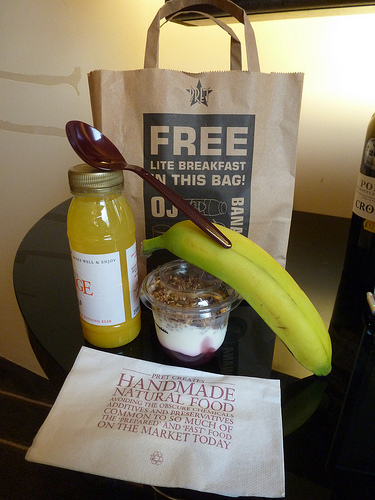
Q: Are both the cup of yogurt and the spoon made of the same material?
A: Yes, both the cup and the spoon are made of plastic.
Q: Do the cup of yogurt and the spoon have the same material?
A: Yes, both the cup and the spoon are made of plastic.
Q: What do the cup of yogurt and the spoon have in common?
A: The material, both the cup and the spoon are plastic.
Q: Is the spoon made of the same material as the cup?
A: Yes, both the spoon and the cup are made of plastic.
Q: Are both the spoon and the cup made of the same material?
A: Yes, both the spoon and the cup are made of plastic.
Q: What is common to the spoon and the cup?
A: The material, both the spoon and the cup are plastic.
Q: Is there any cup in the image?
A: Yes, there is a cup.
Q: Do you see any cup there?
A: Yes, there is a cup.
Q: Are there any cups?
A: Yes, there is a cup.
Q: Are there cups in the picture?
A: Yes, there is a cup.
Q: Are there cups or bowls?
A: Yes, there is a cup.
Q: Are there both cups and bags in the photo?
A: Yes, there are both a cup and a bag.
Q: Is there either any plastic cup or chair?
A: Yes, there is a plastic cup.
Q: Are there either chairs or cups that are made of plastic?
A: Yes, the cup is made of plastic.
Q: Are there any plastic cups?
A: Yes, there is a cup that is made of plastic.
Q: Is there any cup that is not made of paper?
A: Yes, there is a cup that is made of plastic.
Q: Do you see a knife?
A: No, there are no knives.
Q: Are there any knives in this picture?
A: No, there are no knives.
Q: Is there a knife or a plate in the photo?
A: No, there are no knives or plates.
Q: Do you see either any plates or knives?
A: No, there are no knives or plates.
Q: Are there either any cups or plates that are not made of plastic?
A: No, there is a cup but it is made of plastic.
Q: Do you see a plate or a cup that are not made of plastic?
A: No, there is a cup but it is made of plastic.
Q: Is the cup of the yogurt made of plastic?
A: Yes, the cup is made of plastic.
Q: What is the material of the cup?
A: The cup is made of plastic.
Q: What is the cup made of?
A: The cup is made of plastic.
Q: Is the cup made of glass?
A: No, the cup is made of plastic.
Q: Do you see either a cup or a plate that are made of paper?
A: No, there is a cup but it is made of plastic.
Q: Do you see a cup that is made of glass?
A: No, there is a cup but it is made of plastic.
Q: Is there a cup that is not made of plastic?
A: No, there is a cup but it is made of plastic.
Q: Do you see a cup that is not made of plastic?
A: No, there is a cup but it is made of plastic.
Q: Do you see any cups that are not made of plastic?
A: No, there is a cup but it is made of plastic.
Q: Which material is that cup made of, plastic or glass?
A: The cup is made of plastic.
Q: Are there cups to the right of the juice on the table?
A: Yes, there is a cup to the right of the juice.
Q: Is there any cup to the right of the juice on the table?
A: Yes, there is a cup to the right of the juice.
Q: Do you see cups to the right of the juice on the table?
A: Yes, there is a cup to the right of the juice.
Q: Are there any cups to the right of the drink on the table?
A: Yes, there is a cup to the right of the juice.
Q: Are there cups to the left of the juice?
A: No, the cup is to the right of the juice.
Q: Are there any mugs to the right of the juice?
A: No, there is a cup to the right of the juice.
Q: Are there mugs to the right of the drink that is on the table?
A: No, there is a cup to the right of the juice.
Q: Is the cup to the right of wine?
A: No, the cup is to the right of the juice.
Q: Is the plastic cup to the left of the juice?
A: No, the cup is to the right of the juice.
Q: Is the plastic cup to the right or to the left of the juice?
A: The cup is to the right of the juice.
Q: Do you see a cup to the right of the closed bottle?
A: Yes, there is a cup to the right of the bottle.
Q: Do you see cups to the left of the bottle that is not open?
A: No, the cup is to the right of the bottle.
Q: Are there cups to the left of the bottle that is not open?
A: No, the cup is to the right of the bottle.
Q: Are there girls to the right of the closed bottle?
A: No, there is a cup to the right of the bottle.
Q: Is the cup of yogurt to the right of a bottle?
A: Yes, the cup is to the right of a bottle.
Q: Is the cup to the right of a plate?
A: No, the cup is to the right of a bottle.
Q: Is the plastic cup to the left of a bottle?
A: No, the cup is to the right of a bottle.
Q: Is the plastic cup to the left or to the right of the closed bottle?
A: The cup is to the right of the bottle.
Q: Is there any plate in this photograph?
A: No, there are no plates.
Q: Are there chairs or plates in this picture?
A: No, there are no plates or chairs.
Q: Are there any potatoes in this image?
A: No, there are no potatoes.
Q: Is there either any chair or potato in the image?
A: No, there are no potatoes or chairs.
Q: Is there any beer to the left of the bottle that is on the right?
A: No, there is breakfast to the left of the bottle.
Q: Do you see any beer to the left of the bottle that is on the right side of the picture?
A: No, there is breakfast to the left of the bottle.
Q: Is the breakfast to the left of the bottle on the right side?
A: Yes, the breakfast is to the left of the bottle.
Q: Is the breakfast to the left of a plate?
A: No, the breakfast is to the left of the bottle.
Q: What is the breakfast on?
A: The breakfast is on the table.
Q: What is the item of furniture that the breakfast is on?
A: The piece of furniture is a table.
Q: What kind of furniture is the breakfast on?
A: The breakfast is on the table.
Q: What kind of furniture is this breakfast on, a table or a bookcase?
A: The breakfast is on a table.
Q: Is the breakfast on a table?
A: Yes, the breakfast is on a table.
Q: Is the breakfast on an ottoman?
A: No, the breakfast is on a table.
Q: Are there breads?
A: No, there are no breads.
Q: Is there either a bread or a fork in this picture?
A: No, there are no breads or forks.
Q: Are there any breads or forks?
A: No, there are no breads or forks.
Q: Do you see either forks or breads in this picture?
A: No, there are no breads or forks.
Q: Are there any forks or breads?
A: No, there are no breads or forks.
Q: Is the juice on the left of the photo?
A: Yes, the juice is on the left of the image.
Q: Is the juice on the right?
A: No, the juice is on the left of the image.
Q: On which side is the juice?
A: The juice is on the left of the image.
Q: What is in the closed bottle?
A: The juice is in the bottle.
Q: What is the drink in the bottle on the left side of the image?
A: The drink is juice.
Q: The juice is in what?
A: The juice is in the bottle.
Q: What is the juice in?
A: The juice is in the bottle.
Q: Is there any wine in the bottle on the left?
A: No, there is juice in the bottle.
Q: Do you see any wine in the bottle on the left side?
A: No, there is juice in the bottle.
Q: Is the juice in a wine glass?
A: No, the juice is in a bottle.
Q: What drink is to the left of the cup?
A: The drink is juice.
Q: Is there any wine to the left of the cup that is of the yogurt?
A: No, there is juice to the left of the cup.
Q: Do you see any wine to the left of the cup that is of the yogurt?
A: No, there is juice to the left of the cup.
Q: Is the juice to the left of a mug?
A: No, the juice is to the left of the cup.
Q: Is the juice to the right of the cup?
A: No, the juice is to the left of the cup.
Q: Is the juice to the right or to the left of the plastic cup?
A: The juice is to the left of the cup.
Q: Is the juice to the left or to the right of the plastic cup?
A: The juice is to the left of the cup.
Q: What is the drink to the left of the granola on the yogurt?
A: The drink is juice.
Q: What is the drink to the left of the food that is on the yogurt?
A: The drink is juice.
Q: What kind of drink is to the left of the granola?
A: The drink is juice.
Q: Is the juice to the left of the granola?
A: Yes, the juice is to the left of the granola.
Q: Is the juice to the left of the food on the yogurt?
A: Yes, the juice is to the left of the granola.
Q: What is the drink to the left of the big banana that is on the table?
A: The drink is juice.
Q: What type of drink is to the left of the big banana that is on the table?
A: The drink is juice.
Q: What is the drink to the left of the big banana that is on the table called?
A: The drink is juice.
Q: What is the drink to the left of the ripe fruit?
A: The drink is juice.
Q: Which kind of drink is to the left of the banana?
A: The drink is juice.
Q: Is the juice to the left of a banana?
A: Yes, the juice is to the left of a banana.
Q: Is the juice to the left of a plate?
A: No, the juice is to the left of a banana.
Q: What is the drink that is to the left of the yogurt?
A: The drink is juice.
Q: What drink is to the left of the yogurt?
A: The drink is juice.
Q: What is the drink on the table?
A: The drink is juice.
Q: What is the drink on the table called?
A: The drink is juice.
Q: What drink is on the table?
A: The drink is juice.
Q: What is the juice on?
A: The juice is on the table.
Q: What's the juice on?
A: The juice is on the table.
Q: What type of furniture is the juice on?
A: The juice is on the table.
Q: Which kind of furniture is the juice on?
A: The juice is on the table.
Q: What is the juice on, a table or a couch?
A: The juice is on a table.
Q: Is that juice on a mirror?
A: No, the juice is on a table.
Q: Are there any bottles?
A: Yes, there is a bottle.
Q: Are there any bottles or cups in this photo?
A: Yes, there is a bottle.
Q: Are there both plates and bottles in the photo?
A: No, there is a bottle but no plates.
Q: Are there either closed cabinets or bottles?
A: Yes, there is a closed bottle.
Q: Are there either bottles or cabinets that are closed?
A: Yes, the bottle is closed.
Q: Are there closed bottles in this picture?
A: Yes, there is a closed bottle.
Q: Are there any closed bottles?
A: Yes, there is a closed bottle.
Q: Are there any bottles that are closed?
A: Yes, there is a bottle that is closed.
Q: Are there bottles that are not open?
A: Yes, there is an closed bottle.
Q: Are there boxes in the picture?
A: No, there are no boxes.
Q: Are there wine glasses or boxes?
A: No, there are no boxes or wine glasses.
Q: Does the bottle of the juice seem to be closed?
A: Yes, the bottle is closed.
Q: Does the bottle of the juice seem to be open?
A: No, the bottle is closed.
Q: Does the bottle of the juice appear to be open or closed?
A: The bottle is closed.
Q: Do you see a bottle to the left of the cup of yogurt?
A: Yes, there is a bottle to the left of the cup.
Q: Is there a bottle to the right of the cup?
A: No, the bottle is to the left of the cup.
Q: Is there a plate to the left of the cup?
A: No, there is a bottle to the left of the cup.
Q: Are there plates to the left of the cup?
A: No, there is a bottle to the left of the cup.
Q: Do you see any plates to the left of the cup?
A: No, there is a bottle to the left of the cup.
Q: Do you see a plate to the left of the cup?
A: No, there is a bottle to the left of the cup.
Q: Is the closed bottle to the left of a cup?
A: Yes, the bottle is to the left of a cup.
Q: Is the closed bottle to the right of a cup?
A: No, the bottle is to the left of a cup.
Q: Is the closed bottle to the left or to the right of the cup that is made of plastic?
A: The bottle is to the left of the cup.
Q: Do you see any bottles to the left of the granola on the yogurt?
A: Yes, there is a bottle to the left of the granola.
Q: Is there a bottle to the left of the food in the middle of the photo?
A: Yes, there is a bottle to the left of the granola.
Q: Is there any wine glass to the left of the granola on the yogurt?
A: No, there is a bottle to the left of the granola.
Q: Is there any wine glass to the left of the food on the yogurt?
A: No, there is a bottle to the left of the granola.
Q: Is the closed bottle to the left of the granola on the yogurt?
A: Yes, the bottle is to the left of the granola.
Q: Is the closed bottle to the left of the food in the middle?
A: Yes, the bottle is to the left of the granola.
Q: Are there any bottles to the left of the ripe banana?
A: Yes, there is a bottle to the left of the banana.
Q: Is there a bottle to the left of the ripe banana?
A: Yes, there is a bottle to the left of the banana.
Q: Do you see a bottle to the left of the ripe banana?
A: Yes, there is a bottle to the left of the banana.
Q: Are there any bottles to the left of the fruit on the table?
A: Yes, there is a bottle to the left of the banana.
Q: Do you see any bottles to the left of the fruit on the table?
A: Yes, there is a bottle to the left of the banana.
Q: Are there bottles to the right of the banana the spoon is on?
A: No, the bottle is to the left of the banana.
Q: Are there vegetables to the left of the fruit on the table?
A: No, there is a bottle to the left of the banana.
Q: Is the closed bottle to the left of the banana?
A: Yes, the bottle is to the left of the banana.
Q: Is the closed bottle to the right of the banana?
A: No, the bottle is to the left of the banana.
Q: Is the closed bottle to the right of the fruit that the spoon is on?
A: No, the bottle is to the left of the banana.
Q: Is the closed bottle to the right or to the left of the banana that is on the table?
A: The bottle is to the left of the banana.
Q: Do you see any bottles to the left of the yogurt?
A: Yes, there is a bottle to the left of the yogurt.